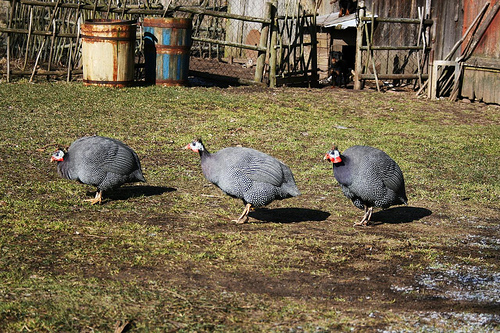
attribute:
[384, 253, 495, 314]
cereals — white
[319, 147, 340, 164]
face — red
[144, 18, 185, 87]
tank — small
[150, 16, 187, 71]
barrel — rusty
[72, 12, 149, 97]
barrel — rusty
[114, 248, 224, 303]
ground — bare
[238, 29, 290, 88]
poles — wooden